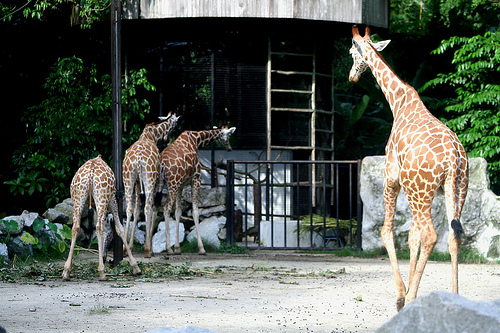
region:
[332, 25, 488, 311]
tall brown spotted giraffe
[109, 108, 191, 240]
tall brown spotted giraffe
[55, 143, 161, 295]
tall brown spotted giraffe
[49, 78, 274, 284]
three brown spotted giraffes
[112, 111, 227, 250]
two brown spotted giraffes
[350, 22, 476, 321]
one spotted brown giraffe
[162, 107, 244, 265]
one spotted brown giraffe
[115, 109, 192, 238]
one spotted brown giraffe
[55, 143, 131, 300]
one spotted brown giraffe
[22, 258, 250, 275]
leaves on the ground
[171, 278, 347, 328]
rocks on the ground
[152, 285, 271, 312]
a stick on the ground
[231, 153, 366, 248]
a black steel fence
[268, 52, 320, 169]
a silver ladder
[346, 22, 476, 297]
a tall giraffe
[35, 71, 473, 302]
giraffes that are standing behind a fence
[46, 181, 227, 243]
rocks next to the giraffes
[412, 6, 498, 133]
green leaves on the tree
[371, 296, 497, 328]
a big rock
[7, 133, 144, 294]
this is a giraffe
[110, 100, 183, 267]
this is a giraffe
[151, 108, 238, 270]
this is a giraffe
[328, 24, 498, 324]
this is a giraffe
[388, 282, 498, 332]
this is a rock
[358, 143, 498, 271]
this is a rock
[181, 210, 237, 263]
this is a rock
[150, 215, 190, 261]
this is a rock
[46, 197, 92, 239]
this is a rock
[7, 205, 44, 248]
this is a rock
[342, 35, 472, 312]
the giraffe is taking a step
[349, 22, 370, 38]
the giraffe has small horns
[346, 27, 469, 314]
the giraffe is polka dot in pattern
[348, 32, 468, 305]
the giraffe is brown and white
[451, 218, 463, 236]
the end of the giraffe's tail is black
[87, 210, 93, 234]
the end of the giraffe's tail is black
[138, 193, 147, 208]
the end of the giraffe's tail is black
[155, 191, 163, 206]
the end of the giraffe's tail is black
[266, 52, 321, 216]
a ladder is in the back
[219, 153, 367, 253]
a metal fence is in the back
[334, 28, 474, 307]
a tall giraffe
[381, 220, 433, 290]
the giraffes legs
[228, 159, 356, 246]
a gate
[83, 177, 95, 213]
the giraffes tail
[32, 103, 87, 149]
the green leaves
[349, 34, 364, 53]
the giraffes ear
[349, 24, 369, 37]
horns on the giraffe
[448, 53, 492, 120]
the leaves are green on the bush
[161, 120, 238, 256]
Giraffe standing in the pin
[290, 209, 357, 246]
Grass in the yard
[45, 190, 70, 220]
rock in the pin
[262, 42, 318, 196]
ladder on the building